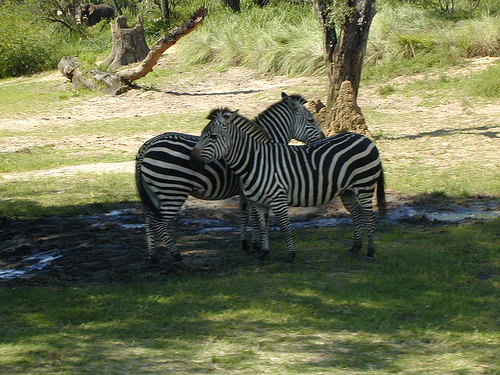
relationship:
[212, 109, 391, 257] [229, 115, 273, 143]
zebra has mane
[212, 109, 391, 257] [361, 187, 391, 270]
zebra has leg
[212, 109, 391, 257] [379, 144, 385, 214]
zebra has tail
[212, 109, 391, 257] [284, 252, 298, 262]
zebra has hoof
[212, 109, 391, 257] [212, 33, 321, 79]
zebra on grass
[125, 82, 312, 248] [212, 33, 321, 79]
zebra on grass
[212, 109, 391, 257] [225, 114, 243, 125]
zebra has ear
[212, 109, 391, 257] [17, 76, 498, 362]
zebra in field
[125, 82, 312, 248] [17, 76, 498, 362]
zebra in field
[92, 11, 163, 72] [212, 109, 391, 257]
tree behind zebra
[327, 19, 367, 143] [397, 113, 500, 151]
tree has shadow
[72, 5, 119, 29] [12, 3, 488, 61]
elephant in background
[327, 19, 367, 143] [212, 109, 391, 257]
tree behind zebra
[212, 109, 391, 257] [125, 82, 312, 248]
zebra next to zebra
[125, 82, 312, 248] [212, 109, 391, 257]
zebra next to zebra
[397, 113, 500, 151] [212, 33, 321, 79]
shadow on grass